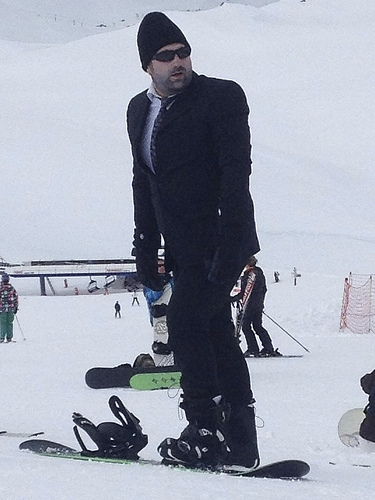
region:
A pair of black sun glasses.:
[148, 44, 190, 61]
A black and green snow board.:
[18, 437, 308, 474]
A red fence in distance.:
[335, 270, 369, 331]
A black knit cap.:
[135, 8, 187, 68]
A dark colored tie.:
[131, 90, 177, 174]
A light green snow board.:
[129, 371, 180, 387]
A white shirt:
[144, 81, 191, 176]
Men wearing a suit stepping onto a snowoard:
[17, 11, 311, 478]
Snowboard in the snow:
[20, 436, 310, 475]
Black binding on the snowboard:
[73, 393, 149, 459]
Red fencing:
[339, 272, 373, 336]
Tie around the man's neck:
[151, 93, 172, 168]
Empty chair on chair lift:
[88, 273, 101, 294]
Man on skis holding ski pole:
[232, 251, 310, 360]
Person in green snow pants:
[0, 272, 27, 348]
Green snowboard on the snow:
[128, 369, 196, 387]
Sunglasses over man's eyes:
[151, 43, 191, 60]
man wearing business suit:
[105, 4, 285, 465]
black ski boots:
[146, 387, 264, 474]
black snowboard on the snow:
[20, 426, 297, 484]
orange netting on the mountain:
[333, 269, 367, 332]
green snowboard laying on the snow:
[130, 368, 184, 387]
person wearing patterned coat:
[1, 274, 24, 344]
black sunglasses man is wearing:
[153, 48, 191, 65]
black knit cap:
[133, 8, 194, 55]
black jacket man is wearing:
[113, 78, 249, 264]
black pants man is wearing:
[156, 252, 246, 419]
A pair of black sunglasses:
[148, 41, 193, 65]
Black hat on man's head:
[133, 8, 198, 95]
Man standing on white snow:
[2, 8, 372, 493]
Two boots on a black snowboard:
[16, 398, 312, 483]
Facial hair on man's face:
[144, 58, 196, 95]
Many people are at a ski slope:
[0, 5, 372, 493]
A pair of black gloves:
[131, 240, 245, 291]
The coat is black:
[123, 68, 264, 259]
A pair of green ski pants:
[0, 308, 18, 340]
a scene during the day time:
[7, 10, 373, 490]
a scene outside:
[8, 0, 331, 491]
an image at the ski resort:
[0, 7, 362, 491]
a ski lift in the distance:
[0, 240, 178, 306]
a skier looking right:
[118, 3, 316, 496]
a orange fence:
[322, 262, 372, 345]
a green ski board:
[120, 359, 202, 395]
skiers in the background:
[1, 219, 352, 490]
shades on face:
[145, 42, 198, 73]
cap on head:
[130, 5, 194, 78]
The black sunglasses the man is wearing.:
[152, 50, 192, 58]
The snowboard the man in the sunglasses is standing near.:
[22, 443, 305, 478]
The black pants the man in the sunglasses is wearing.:
[175, 234, 244, 402]